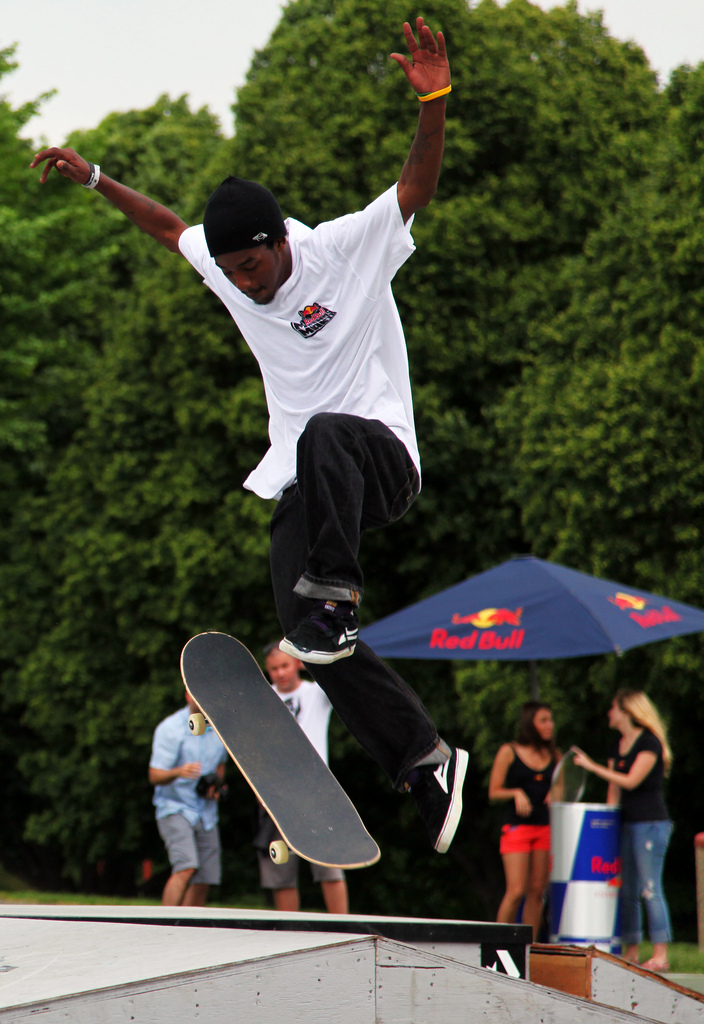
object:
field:
[0, 0, 702, 1024]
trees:
[0, 0, 701, 923]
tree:
[473, 2, 702, 933]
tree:
[24, 0, 637, 923]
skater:
[26, 14, 473, 874]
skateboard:
[173, 630, 381, 874]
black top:
[613, 729, 671, 822]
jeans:
[613, 819, 678, 943]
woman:
[570, 687, 672, 974]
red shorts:
[498, 819, 552, 854]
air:
[166, 613, 392, 878]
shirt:
[177, 176, 423, 497]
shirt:
[149, 706, 225, 829]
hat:
[203, 175, 287, 258]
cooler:
[547, 751, 621, 961]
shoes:
[278, 595, 469, 855]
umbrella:
[343, 553, 701, 670]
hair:
[618, 687, 673, 782]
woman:
[487, 695, 563, 942]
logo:
[428, 605, 528, 652]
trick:
[27, 14, 481, 874]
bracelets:
[416, 83, 452, 102]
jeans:
[269, 413, 438, 786]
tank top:
[497, 744, 559, 824]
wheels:
[186, 709, 290, 865]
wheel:
[186, 710, 205, 737]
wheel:
[268, 840, 291, 867]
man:
[260, 633, 351, 924]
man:
[148, 681, 227, 909]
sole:
[278, 636, 361, 664]